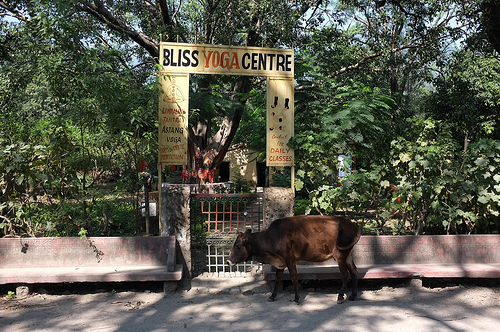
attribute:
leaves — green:
[347, 89, 394, 129]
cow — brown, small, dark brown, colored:
[224, 209, 371, 310]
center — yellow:
[150, 35, 301, 295]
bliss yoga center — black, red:
[159, 43, 298, 78]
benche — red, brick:
[1, 231, 187, 295]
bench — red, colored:
[365, 228, 499, 287]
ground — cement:
[0, 289, 498, 328]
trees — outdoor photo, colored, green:
[7, 9, 491, 226]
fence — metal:
[191, 194, 236, 277]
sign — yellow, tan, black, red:
[156, 39, 301, 173]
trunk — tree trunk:
[210, 81, 251, 150]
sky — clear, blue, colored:
[9, 7, 490, 87]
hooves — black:
[266, 292, 358, 309]